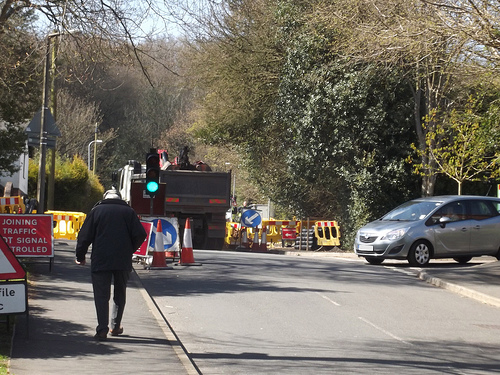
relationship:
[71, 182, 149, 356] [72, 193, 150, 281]
man wearing a jacket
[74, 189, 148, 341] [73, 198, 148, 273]
man wears jacket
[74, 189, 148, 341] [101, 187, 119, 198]
man in hat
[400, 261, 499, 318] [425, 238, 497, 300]
curb on sidewalk